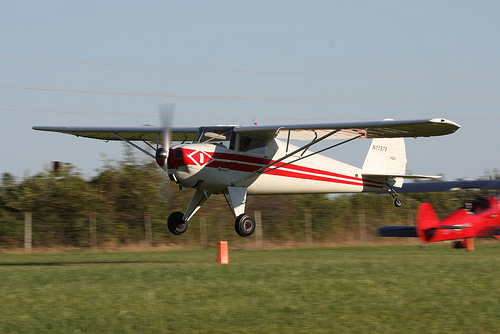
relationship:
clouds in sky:
[29, 22, 111, 84] [1, 1, 498, 168]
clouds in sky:
[1, 58, 71, 121] [13, 4, 494, 104]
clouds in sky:
[111, 32, 234, 94] [2, 0, 497, 209]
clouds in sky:
[238, 65, 310, 109] [15, 15, 472, 126]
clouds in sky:
[111, 37, 207, 87] [2, 0, 497, 117]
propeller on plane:
[100, 105, 217, 210] [26, 104, 463, 237]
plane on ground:
[376, 194, 497, 256] [1, 250, 499, 331]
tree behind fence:
[0, 161, 115, 236] [258, 206, 386, 243]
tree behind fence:
[91, 161, 168, 220] [258, 206, 386, 243]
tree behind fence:
[249, 192, 332, 212] [258, 206, 386, 243]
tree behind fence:
[330, 193, 387, 211] [258, 206, 386, 243]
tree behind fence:
[421, 189, 458, 215] [258, 206, 386, 243]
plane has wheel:
[26, 104, 463, 237] [166, 210, 188, 233]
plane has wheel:
[26, 104, 463, 237] [234, 212, 255, 236]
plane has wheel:
[26, 104, 463, 237] [394, 197, 401, 206]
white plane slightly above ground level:
[27, 116, 463, 236] [1, 249, 498, 331]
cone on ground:
[205, 234, 243, 279] [1, 250, 499, 331]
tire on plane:
[231, 211, 258, 240] [26, 104, 463, 237]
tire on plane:
[164, 208, 189, 236] [26, 104, 463, 237]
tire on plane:
[392, 195, 404, 210] [26, 104, 463, 237]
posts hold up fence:
[23, 214, 95, 250] [290, 212, 341, 236]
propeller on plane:
[157, 99, 174, 199] [26, 104, 463, 237]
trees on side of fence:
[8, 171, 498, 254] [0, 207, 500, 250]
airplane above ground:
[27, 116, 460, 236] [1, 250, 499, 331]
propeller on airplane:
[151, 99, 176, 201] [33, 97, 458, 237]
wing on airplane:
[30, 113, 460, 140] [33, 97, 458, 237]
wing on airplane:
[28, 107, 162, 175] [28, 46, 498, 241]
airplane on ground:
[33, 97, 458, 237] [1, 250, 499, 331]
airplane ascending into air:
[27, 116, 460, 236] [1, 0, 499, 113]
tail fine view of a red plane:
[402, 108, 452, 238] [26, 81, 458, 271]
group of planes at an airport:
[44, 130, 496, 176] [9, 88, 497, 334]